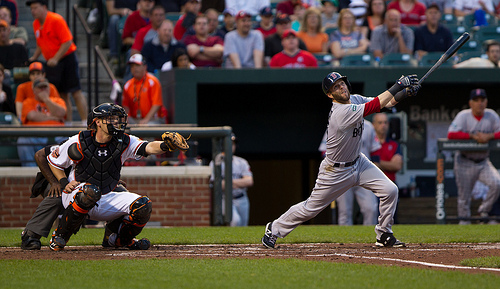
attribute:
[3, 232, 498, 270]
dirt — brown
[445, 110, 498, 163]
shirt — white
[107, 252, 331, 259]
lines — white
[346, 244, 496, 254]
lines — white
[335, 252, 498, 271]
lines — white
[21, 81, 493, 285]
area — grassy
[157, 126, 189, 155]
mitt — black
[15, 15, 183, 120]
shirts — orange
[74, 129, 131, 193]
protector — black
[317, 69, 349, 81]
helmet — black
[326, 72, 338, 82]
emblem — white, red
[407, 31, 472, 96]
baseball bat — black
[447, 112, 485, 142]
shirt — long sleeved, red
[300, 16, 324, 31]
hair — red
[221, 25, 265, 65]
shirt — gray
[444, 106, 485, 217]
outfit — baseball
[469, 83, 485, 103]
cap — baseball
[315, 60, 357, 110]
head — batter's